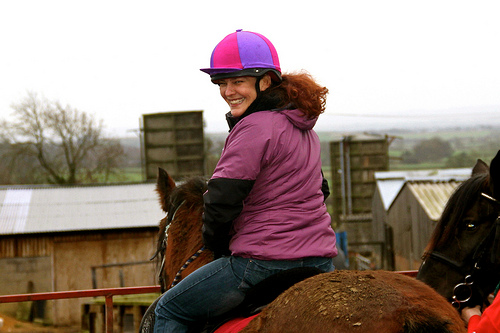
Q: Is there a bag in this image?
A: No, there are no bags.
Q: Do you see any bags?
A: No, there are no bags.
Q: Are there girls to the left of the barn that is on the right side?
A: Yes, there is a girl to the left of the barn.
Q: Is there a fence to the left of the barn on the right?
A: No, there is a girl to the left of the barn.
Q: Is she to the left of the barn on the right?
A: Yes, the girl is to the left of the barn.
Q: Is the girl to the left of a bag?
A: No, the girl is to the left of the barn.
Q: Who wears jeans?
A: The girl wears jeans.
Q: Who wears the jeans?
A: The girl wears jeans.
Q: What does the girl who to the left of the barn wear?
A: The girl wears jeans.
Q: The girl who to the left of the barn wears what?
A: The girl wears jeans.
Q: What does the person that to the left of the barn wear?
A: The girl wears jeans.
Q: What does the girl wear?
A: The girl wears jeans.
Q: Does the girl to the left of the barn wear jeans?
A: Yes, the girl wears jeans.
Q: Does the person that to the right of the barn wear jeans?
A: Yes, the girl wears jeans.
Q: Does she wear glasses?
A: No, the girl wears jeans.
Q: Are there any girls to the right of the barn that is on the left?
A: Yes, there is a girl to the right of the barn.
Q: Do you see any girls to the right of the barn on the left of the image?
A: Yes, there is a girl to the right of the barn.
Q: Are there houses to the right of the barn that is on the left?
A: No, there is a girl to the right of the barn.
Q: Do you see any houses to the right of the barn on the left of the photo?
A: No, there is a girl to the right of the barn.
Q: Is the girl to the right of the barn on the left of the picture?
A: Yes, the girl is to the right of the barn.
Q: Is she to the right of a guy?
A: No, the girl is to the right of the barn.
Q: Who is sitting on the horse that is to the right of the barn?
A: The girl is sitting on the horse.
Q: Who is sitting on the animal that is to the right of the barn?
A: The girl is sitting on the horse.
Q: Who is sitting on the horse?
A: The girl is sitting on the horse.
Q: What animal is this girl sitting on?
A: The girl is sitting on the horse.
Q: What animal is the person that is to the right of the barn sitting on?
A: The girl is sitting on the horse.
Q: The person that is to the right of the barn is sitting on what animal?
A: The girl is sitting on the horse.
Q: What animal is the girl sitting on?
A: The girl is sitting on the horse.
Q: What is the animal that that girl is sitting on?
A: The animal is a horse.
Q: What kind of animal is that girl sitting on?
A: The girl is sitting on the horse.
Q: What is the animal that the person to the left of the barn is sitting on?
A: The animal is a horse.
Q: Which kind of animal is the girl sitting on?
A: The girl is sitting on the horse.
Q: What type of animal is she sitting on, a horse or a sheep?
A: The girl is sitting on a horse.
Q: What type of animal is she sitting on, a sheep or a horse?
A: The girl is sitting on a horse.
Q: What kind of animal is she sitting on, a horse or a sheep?
A: The girl is sitting on a horse.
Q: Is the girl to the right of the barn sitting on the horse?
A: Yes, the girl is sitting on the horse.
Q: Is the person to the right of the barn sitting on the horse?
A: Yes, the girl is sitting on the horse.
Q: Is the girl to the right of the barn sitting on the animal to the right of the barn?
A: Yes, the girl is sitting on the horse.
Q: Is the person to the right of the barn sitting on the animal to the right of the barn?
A: Yes, the girl is sitting on the horse.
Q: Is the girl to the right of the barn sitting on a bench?
A: No, the girl is sitting on the horse.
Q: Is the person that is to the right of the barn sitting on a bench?
A: No, the girl is sitting on the horse.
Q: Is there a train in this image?
A: No, there are no trains.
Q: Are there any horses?
A: Yes, there is a horse.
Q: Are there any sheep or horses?
A: Yes, there is a horse.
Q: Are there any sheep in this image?
A: No, there are no sheep.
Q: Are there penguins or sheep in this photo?
A: No, there are no sheep or penguins.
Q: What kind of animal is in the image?
A: The animal is a horse.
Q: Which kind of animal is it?
A: The animal is a horse.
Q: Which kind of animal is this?
A: This is a horse.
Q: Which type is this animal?
A: This is a horse.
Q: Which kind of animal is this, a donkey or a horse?
A: This is a horse.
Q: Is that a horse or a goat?
A: That is a horse.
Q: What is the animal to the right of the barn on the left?
A: The animal is a horse.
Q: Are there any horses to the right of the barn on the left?
A: Yes, there is a horse to the right of the barn.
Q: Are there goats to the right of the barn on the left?
A: No, there is a horse to the right of the barn.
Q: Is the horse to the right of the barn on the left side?
A: Yes, the horse is to the right of the barn.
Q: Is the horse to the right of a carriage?
A: No, the horse is to the right of the barn.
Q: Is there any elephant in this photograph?
A: No, there are no elephants.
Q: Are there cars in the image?
A: No, there are no cars.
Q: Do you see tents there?
A: No, there are no tents.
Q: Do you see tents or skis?
A: No, there are no tents or skis.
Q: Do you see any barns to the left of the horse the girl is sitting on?
A: Yes, there is a barn to the left of the horse.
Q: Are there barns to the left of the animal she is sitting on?
A: Yes, there is a barn to the left of the horse.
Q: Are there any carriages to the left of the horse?
A: No, there is a barn to the left of the horse.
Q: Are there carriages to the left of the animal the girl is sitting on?
A: No, there is a barn to the left of the horse.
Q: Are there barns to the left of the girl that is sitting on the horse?
A: Yes, there is a barn to the left of the girl.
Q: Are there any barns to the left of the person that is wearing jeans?
A: Yes, there is a barn to the left of the girl.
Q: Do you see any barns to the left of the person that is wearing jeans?
A: Yes, there is a barn to the left of the girl.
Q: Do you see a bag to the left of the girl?
A: No, there is a barn to the left of the girl.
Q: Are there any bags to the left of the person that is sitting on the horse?
A: No, there is a barn to the left of the girl.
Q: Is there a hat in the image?
A: Yes, there is a hat.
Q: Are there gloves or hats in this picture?
A: Yes, there is a hat.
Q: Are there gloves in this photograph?
A: No, there are no gloves.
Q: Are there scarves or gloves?
A: No, there are no gloves or scarves.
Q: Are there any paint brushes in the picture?
A: No, there are no paint brushes.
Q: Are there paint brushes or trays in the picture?
A: No, there are no paint brushes or trays.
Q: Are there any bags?
A: No, there are no bags.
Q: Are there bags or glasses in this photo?
A: No, there are no bags or glasses.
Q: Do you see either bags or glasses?
A: No, there are no bags or glasses.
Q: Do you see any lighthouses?
A: No, there are no lighthouses.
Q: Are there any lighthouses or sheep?
A: No, there are no lighthouses or sheep.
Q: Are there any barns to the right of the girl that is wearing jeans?
A: Yes, there is a barn to the right of the girl.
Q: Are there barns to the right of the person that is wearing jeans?
A: Yes, there is a barn to the right of the girl.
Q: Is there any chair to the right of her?
A: No, there is a barn to the right of the girl.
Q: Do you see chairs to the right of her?
A: No, there is a barn to the right of the girl.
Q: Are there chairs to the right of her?
A: No, there is a barn to the right of the girl.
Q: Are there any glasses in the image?
A: No, there are no glasses.